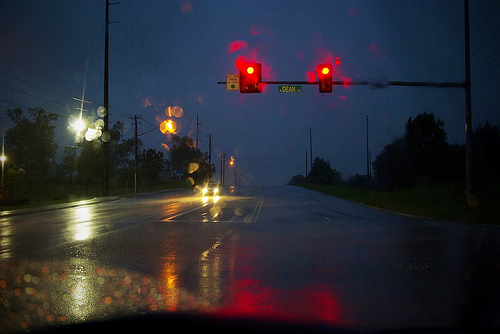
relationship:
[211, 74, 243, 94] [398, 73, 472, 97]
sign attached to pole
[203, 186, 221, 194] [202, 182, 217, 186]
headlights attached to car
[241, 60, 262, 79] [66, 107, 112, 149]
light from lamp post\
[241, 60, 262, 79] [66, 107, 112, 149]
light on top of lamp post\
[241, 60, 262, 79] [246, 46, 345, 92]
light for traffic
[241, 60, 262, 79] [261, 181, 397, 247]
light in street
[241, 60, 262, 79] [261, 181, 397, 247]
light on top of street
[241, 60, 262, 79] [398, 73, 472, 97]
light on top of pole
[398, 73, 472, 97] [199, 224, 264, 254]
pole on side of road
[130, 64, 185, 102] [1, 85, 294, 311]
water on top of windshield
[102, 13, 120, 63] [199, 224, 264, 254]
lines on side of road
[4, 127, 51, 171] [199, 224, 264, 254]
trees on side of road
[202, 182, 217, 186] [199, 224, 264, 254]
car on top of road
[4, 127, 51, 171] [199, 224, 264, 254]
trees running alongise road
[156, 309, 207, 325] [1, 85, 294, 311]
wiper attached to windshield